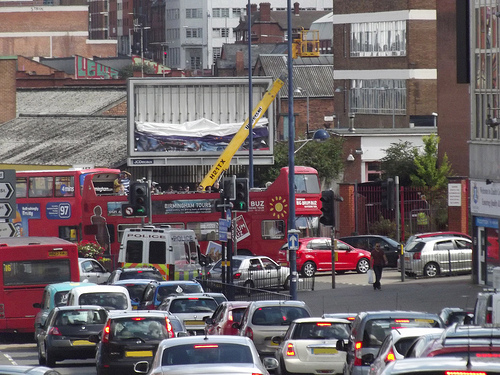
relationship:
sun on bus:
[268, 196, 291, 219] [223, 164, 322, 264]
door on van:
[144, 234, 164, 278] [113, 223, 207, 283]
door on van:
[121, 232, 145, 270] [113, 223, 207, 283]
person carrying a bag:
[367, 242, 392, 295] [368, 265, 379, 284]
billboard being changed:
[126, 75, 278, 168] [132, 116, 271, 151]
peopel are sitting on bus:
[39, 180, 78, 197] [3, 164, 124, 259]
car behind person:
[279, 237, 373, 276] [367, 242, 392, 295]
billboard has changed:
[126, 75, 278, 168] [132, 116, 271, 151]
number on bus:
[58, 201, 71, 217] [3, 164, 124, 259]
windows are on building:
[348, 18, 409, 59] [330, 3, 467, 195]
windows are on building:
[351, 79, 406, 112] [330, 3, 467, 195]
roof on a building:
[3, 92, 126, 165] [1, 81, 130, 171]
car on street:
[279, 237, 373, 276] [289, 255, 472, 286]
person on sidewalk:
[367, 242, 392, 295] [290, 274, 484, 316]